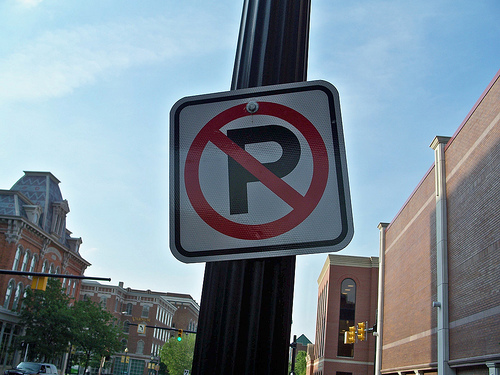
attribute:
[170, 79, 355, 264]
sign — red, white, black, no sign, no parking, left turn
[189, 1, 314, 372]
pole — black, tall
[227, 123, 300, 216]
letter — black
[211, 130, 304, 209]
line` — red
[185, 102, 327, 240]
circle` — red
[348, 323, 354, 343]
light — yellow, traffic signal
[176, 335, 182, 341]
light — green, on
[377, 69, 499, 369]
brick — red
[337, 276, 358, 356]
window — arch shaped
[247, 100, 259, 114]
screw — metal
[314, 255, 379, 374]
building — brown, large, old, brick, red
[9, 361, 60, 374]
vehicle — parked, driving, moving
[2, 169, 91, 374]
building — tall, red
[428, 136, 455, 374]
column — tall